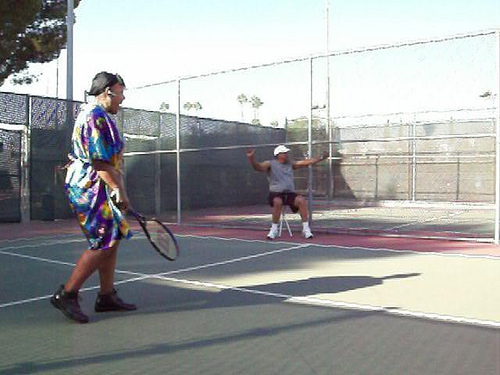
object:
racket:
[111, 191, 179, 260]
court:
[0, 216, 500, 375]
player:
[48, 69, 127, 320]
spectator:
[242, 146, 333, 242]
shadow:
[105, 270, 423, 318]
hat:
[272, 145, 290, 158]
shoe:
[50, 284, 90, 324]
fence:
[0, 93, 284, 225]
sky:
[0, 0, 500, 129]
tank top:
[265, 159, 295, 193]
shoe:
[265, 225, 279, 240]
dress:
[63, 99, 133, 249]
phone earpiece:
[106, 90, 117, 99]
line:
[0, 273, 148, 307]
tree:
[0, 0, 81, 86]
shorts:
[268, 189, 302, 214]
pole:
[325, 73, 337, 198]